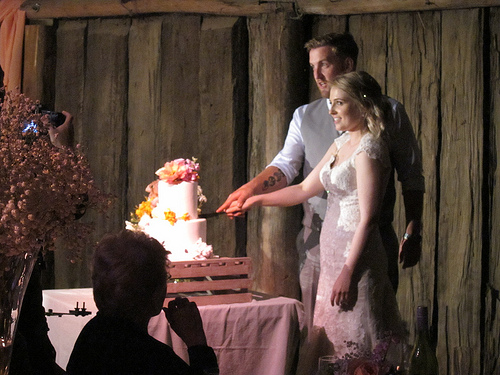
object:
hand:
[216, 191, 248, 219]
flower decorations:
[123, 156, 216, 261]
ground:
[450, 143, 461, 173]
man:
[213, 30, 425, 374]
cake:
[123, 155, 215, 262]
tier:
[136, 216, 214, 260]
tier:
[151, 177, 198, 219]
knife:
[196, 210, 233, 219]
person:
[63, 228, 220, 373]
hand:
[160, 295, 205, 341]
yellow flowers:
[133, 200, 152, 219]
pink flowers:
[143, 155, 208, 206]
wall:
[256, 93, 333, 149]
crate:
[162, 256, 252, 309]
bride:
[225, 69, 404, 374]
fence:
[21, 5, 499, 374]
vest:
[300, 94, 397, 232]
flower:
[0, 84, 118, 277]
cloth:
[41, 287, 305, 374]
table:
[40, 282, 308, 374]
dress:
[308, 129, 404, 374]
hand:
[223, 196, 258, 221]